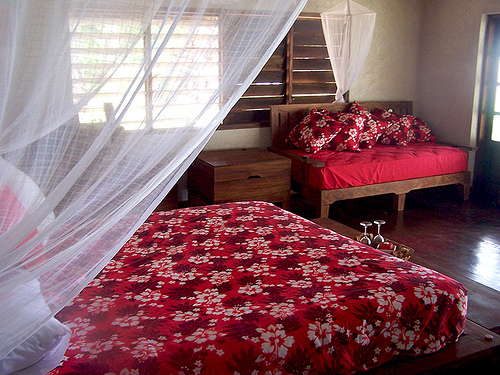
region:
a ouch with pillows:
[212, 56, 497, 244]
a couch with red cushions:
[260, 58, 492, 243]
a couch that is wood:
[251, 75, 492, 250]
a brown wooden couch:
[265, 81, 499, 261]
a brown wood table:
[185, 123, 311, 240]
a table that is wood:
[182, 123, 318, 248]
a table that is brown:
[182, 123, 490, 333]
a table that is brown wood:
[177, 103, 346, 253]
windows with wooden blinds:
[214, 12, 376, 105]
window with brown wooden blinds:
[212, 3, 407, 201]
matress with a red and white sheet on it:
[14, 198, 466, 373]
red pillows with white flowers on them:
[286, 99, 433, 154]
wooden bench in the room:
[270, 94, 469, 219]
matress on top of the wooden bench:
[288, 140, 468, 188]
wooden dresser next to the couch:
[190, 145, 292, 210]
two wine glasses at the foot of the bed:
[354, 220, 386, 245]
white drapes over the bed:
[1, 2, 307, 371]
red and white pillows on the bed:
[0, 158, 71, 374]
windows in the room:
[14, 5, 351, 134]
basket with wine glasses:
[356, 235, 413, 260]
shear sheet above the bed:
[4, 0, 310, 356]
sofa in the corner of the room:
[279, 99, 468, 206]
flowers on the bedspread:
[169, 241, 356, 334]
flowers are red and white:
[196, 226, 330, 331]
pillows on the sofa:
[299, 108, 444, 137]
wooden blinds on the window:
[224, 18, 362, 119]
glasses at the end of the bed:
[349, 209, 408, 256]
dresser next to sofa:
[200, 158, 308, 213]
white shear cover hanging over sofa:
[323, 3, 378, 106]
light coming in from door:
[477, 31, 498, 143]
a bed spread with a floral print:
[146, 264, 360, 361]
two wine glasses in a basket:
[357, 217, 383, 243]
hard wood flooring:
[444, 203, 494, 289]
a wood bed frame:
[306, 94, 453, 214]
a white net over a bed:
[9, 2, 314, 259]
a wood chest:
[196, 144, 296, 216]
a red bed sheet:
[304, 134, 456, 196]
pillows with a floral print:
[296, 106, 429, 160]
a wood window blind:
[218, 12, 329, 129]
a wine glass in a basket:
[354, 217, 375, 254]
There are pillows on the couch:
[273, 97, 468, 218]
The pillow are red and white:
[292, 103, 429, 152]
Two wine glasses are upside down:
[356, 218, 392, 248]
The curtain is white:
[1, 4, 303, 352]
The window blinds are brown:
[221, 16, 346, 124]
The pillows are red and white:
[3, 160, 76, 369]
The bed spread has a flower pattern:
[38, 203, 468, 372]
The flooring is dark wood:
[347, 187, 492, 281]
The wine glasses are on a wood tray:
[351, 220, 415, 261]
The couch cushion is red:
[289, 138, 470, 195]